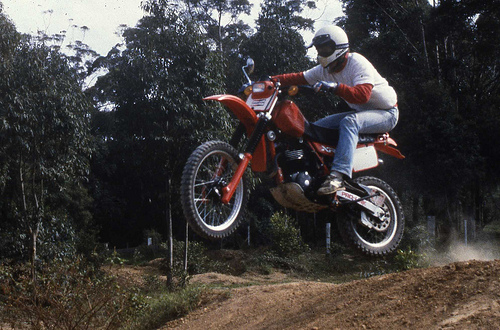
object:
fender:
[375, 144, 406, 159]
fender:
[202, 94, 266, 172]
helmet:
[306, 25, 350, 68]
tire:
[178, 140, 248, 241]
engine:
[285, 148, 312, 191]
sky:
[0, 0, 480, 143]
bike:
[179, 58, 407, 257]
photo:
[0, 0, 499, 330]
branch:
[12, 36, 132, 261]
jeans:
[313, 107, 399, 179]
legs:
[330, 107, 399, 179]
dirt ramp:
[156, 258, 500, 329]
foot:
[317, 170, 347, 195]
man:
[269, 25, 400, 195]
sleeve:
[271, 71, 310, 87]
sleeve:
[335, 83, 373, 104]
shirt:
[303, 52, 398, 111]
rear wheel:
[337, 176, 406, 258]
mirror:
[245, 57, 254, 74]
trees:
[0, 0, 499, 291]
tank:
[271, 99, 311, 138]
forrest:
[1, 6, 500, 330]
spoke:
[194, 154, 236, 226]